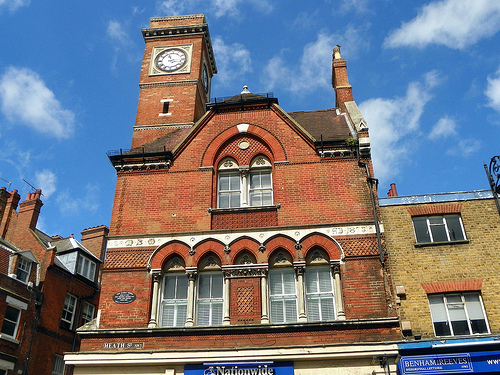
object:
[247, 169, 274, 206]
window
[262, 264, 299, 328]
window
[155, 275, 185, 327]
window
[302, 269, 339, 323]
window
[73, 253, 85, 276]
window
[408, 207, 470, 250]
blue board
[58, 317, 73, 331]
window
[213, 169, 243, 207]
window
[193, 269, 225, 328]
window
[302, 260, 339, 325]
window